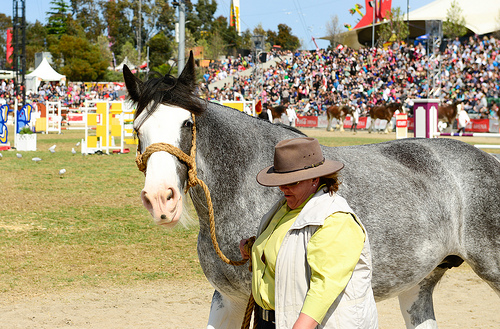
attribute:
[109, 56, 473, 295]
black horse —  black , Grey, white 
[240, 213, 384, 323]
button down — Neon yellow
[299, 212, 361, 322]
sleeve — three-quarter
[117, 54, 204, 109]
hair — Black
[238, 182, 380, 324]
vest — White 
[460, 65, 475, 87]
fan — large group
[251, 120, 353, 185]
hat — Brown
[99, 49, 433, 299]
horse — gray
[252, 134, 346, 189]
hat — brown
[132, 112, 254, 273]
rope — Tan 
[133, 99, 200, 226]
face — horses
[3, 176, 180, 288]
grass — green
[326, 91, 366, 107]
fans — large amount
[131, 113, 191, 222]
face — white, black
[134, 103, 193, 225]
face — White 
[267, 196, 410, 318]
vest — open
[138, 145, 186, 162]
rope — yellowish-gold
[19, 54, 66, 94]
concessions tent — white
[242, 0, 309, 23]
sky — blue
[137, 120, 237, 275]
rope — beige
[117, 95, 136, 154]
pole — white , yellow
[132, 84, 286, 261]
horse — Grey, black , white 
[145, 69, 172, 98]
mane — black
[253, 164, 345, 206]
head — woman's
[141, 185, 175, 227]
nose — Pink 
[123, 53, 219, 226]
head — horse's